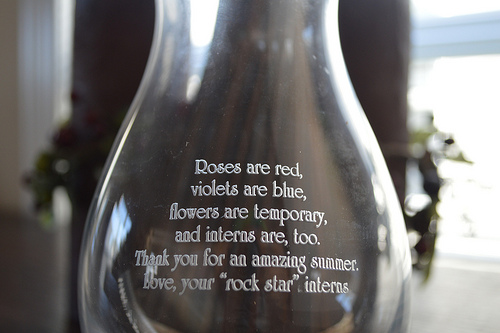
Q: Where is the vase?
A: On a table.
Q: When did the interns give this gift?
A: End of summer.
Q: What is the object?
A: Vase.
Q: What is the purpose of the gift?
A: Thank you.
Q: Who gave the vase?
A: Interns.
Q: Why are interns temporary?
A: Back to school.